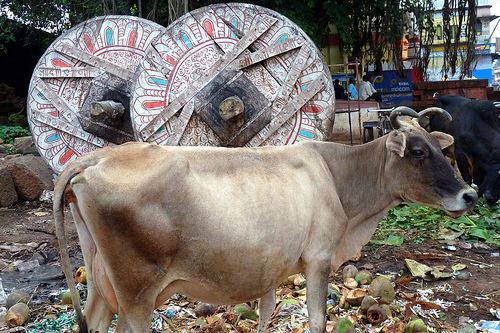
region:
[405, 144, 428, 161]
a cow's right eye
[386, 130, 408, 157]
a cow's right ear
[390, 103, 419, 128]
a cow's right horn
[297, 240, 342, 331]
a cow's right front leg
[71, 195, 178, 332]
a cow's right rear leg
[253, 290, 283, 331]
a cow's left front leg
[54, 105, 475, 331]
a brown cow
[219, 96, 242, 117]
the axle of a large wheel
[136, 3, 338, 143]
a large colorful wheel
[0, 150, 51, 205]
a big rock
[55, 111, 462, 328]
cow in garbage heap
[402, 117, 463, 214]
dark stripe on cow's face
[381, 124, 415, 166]
cow has light brown ears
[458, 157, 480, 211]
black and white nose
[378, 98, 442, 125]
cow has small horns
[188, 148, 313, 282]
cow has large stomach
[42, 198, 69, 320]
cow has light brown tail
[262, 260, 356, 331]
cow has light brown legs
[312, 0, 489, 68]
tree fronds overhang pile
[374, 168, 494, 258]
vegetation lying on ground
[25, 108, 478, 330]
a cow in a pile of trash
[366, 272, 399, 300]
a broken melon on the ground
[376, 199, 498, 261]
a pile of green material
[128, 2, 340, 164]
a large colored wheel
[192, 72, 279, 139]
a black center on the wheel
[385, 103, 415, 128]
the cow has a right horn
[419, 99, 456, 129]
the cow has a left horn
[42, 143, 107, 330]
the cow has a tail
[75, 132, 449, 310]
the cow is bony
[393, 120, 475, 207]
the cow's face is black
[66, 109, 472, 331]
a cow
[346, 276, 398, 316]
fruit on the ground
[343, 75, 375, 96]
two people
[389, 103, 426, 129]
a horn on the cow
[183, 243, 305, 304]
the cows stomach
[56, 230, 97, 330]
the cows tail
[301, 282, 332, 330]
front leg of the cow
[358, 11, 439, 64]
the branches on the tree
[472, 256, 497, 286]
the dirt on the ground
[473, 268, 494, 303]
the dirt is brown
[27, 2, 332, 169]
two large colorful wheels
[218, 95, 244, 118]
the axel of a large wheel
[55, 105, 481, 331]
a skinny looking cow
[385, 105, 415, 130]
the right horn of a cow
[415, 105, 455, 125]
the left horn of a cow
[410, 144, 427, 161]
the right eye of a cow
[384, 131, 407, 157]
the right ear of a cow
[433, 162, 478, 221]
the snout of a cow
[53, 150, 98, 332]
a cow's tail